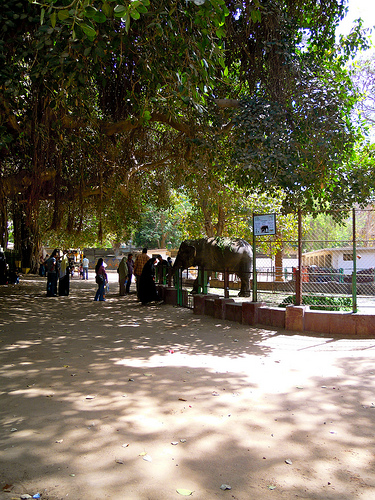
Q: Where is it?
A: This is at the park.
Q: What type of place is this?
A: It is a park.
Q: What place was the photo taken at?
A: It was taken at the park.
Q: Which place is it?
A: It is a park.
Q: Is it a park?
A: Yes, it is a park.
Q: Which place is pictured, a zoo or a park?
A: It is a park.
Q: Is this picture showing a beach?
A: No, the picture is showing a park.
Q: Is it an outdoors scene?
A: Yes, it is outdoors.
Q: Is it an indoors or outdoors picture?
A: It is outdoors.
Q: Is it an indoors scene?
A: No, it is outdoors.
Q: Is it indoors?
A: No, it is outdoors.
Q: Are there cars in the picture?
A: No, there are no cars.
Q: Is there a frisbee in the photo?
A: No, there are no frisbees.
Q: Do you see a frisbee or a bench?
A: No, there are no frisbees or benches.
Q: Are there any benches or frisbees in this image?
A: No, there are no frisbees or benches.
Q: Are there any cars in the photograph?
A: No, there are no cars.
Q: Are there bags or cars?
A: No, there are no cars or bags.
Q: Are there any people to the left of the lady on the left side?
A: No, the person is to the right of the lady.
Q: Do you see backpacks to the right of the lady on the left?
A: No, there is a person to the right of the lady.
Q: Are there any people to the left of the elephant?
A: Yes, there is a person to the left of the elephant.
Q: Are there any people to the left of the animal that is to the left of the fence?
A: Yes, there is a person to the left of the elephant.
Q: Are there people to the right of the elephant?
A: No, the person is to the left of the elephant.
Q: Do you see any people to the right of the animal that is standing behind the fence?
A: No, the person is to the left of the elephant.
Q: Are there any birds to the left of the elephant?
A: No, there is a person to the left of the elephant.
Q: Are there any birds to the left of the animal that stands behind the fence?
A: No, there is a person to the left of the elephant.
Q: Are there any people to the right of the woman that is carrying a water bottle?
A: Yes, there is a person to the right of the woman.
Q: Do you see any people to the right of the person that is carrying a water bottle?
A: Yes, there is a person to the right of the woman.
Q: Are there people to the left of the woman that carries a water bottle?
A: No, the person is to the right of the woman.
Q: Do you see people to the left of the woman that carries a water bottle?
A: No, the person is to the right of the woman.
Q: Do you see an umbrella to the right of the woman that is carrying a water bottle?
A: No, there is a person to the right of the woman.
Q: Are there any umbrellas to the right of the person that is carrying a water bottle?
A: No, there is a person to the right of the woman.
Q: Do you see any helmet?
A: No, there are no helmets.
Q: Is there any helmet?
A: No, there are no helmets.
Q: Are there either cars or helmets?
A: No, there are no helmets or cars.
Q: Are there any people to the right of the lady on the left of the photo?
A: Yes, there is a person to the right of the lady.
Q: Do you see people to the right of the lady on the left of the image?
A: Yes, there is a person to the right of the lady.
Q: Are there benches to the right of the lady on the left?
A: No, there is a person to the right of the lady.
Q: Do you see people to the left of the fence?
A: Yes, there is a person to the left of the fence.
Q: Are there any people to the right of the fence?
A: No, the person is to the left of the fence.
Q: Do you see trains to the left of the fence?
A: No, there is a person to the left of the fence.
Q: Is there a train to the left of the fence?
A: No, there is a person to the left of the fence.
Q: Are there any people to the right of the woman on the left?
A: Yes, there is a person to the right of the woman.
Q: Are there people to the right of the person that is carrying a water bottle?
A: Yes, there is a person to the right of the woman.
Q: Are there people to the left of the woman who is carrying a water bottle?
A: No, the person is to the right of the woman.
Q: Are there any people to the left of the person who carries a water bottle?
A: No, the person is to the right of the woman.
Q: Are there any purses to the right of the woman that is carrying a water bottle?
A: No, there is a person to the right of the woman.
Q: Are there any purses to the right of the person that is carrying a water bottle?
A: No, there is a person to the right of the woman.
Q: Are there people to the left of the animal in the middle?
A: Yes, there is a person to the left of the elephant.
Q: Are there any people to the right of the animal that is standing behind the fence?
A: No, the person is to the left of the elephant.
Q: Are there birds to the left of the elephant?
A: No, there is a person to the left of the elephant.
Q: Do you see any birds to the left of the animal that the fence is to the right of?
A: No, there is a person to the left of the elephant.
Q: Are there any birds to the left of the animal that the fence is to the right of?
A: No, there is a person to the left of the elephant.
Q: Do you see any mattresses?
A: No, there are no mattresses.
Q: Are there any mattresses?
A: No, there are no mattresses.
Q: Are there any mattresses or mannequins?
A: No, there are no mattresses or mannequins.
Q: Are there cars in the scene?
A: No, there are no cars.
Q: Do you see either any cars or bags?
A: No, there are no cars or bags.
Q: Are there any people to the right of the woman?
A: Yes, there are people to the right of the woman.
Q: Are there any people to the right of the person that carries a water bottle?
A: Yes, there are people to the right of the woman.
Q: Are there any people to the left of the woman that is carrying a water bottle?
A: No, the people are to the right of the woman.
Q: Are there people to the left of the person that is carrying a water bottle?
A: No, the people are to the right of the woman.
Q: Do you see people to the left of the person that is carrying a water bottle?
A: No, the people are to the right of the woman.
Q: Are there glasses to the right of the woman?
A: No, there are people to the right of the woman.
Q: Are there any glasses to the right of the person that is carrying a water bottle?
A: No, there are people to the right of the woman.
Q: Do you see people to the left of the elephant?
A: Yes, there are people to the left of the elephant.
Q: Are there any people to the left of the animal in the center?
A: Yes, there are people to the left of the elephant.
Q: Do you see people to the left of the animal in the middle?
A: Yes, there are people to the left of the elephant.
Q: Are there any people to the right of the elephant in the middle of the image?
A: No, the people are to the left of the elephant.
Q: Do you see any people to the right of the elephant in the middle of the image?
A: No, the people are to the left of the elephant.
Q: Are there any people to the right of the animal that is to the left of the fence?
A: No, the people are to the left of the elephant.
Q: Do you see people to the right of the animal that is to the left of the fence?
A: No, the people are to the left of the elephant.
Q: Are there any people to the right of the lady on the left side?
A: Yes, there are people to the right of the lady.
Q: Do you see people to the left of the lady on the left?
A: No, the people are to the right of the lady.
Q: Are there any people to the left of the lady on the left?
A: No, the people are to the right of the lady.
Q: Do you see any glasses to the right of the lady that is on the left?
A: No, there are people to the right of the lady.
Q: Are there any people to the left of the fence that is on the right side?
A: Yes, there are people to the left of the fence.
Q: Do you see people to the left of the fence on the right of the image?
A: Yes, there are people to the left of the fence.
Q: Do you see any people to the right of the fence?
A: No, the people are to the left of the fence.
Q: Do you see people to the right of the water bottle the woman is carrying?
A: Yes, there are people to the right of the water bottle.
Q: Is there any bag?
A: No, there are no bags.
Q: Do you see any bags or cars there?
A: No, there are no bags or cars.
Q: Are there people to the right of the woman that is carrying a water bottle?
A: Yes, there are people to the right of the woman.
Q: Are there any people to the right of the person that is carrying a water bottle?
A: Yes, there are people to the right of the woman.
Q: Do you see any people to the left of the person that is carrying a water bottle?
A: No, the people are to the right of the woman.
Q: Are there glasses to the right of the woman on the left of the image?
A: No, there are people to the right of the woman.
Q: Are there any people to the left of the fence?
A: Yes, there are people to the left of the fence.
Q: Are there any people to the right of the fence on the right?
A: No, the people are to the left of the fence.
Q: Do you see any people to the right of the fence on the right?
A: No, the people are to the left of the fence.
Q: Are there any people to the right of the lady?
A: Yes, there are people to the right of the lady.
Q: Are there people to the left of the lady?
A: No, the people are to the right of the lady.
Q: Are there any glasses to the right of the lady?
A: No, there are people to the right of the lady.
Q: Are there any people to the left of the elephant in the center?
A: Yes, there are people to the left of the elephant.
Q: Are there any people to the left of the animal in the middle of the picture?
A: Yes, there are people to the left of the elephant.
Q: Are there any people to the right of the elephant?
A: No, the people are to the left of the elephant.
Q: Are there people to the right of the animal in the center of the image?
A: No, the people are to the left of the elephant.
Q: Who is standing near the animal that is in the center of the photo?
A: The people are standing near the elephant.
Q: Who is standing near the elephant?
A: The people are standing near the elephant.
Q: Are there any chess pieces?
A: No, there are no chess pieces.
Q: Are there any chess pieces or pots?
A: No, there are no chess pieces or pots.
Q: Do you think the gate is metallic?
A: Yes, the gate is metallic.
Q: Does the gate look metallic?
A: Yes, the gate is metallic.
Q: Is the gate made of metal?
A: Yes, the gate is made of metal.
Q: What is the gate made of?
A: The gate is made of metal.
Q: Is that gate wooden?
A: No, the gate is metallic.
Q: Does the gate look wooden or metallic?
A: The gate is metallic.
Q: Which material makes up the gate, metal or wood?
A: The gate is made of metal.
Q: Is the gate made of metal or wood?
A: The gate is made of metal.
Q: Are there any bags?
A: No, there are no bags.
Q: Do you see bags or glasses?
A: No, there are no bags or glasses.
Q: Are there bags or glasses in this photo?
A: No, there are no bags or glasses.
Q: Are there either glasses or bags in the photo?
A: No, there are no bags or glasses.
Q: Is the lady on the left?
A: Yes, the lady is on the left of the image.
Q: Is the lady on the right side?
A: No, the lady is on the left of the image.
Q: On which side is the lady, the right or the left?
A: The lady is on the left of the image.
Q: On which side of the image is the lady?
A: The lady is on the left of the image.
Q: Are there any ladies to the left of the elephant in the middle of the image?
A: Yes, there is a lady to the left of the elephant.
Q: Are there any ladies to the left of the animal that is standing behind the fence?
A: Yes, there is a lady to the left of the elephant.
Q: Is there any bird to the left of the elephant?
A: No, there is a lady to the left of the elephant.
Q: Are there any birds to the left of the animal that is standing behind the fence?
A: No, there is a lady to the left of the elephant.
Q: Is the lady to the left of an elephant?
A: Yes, the lady is to the left of an elephant.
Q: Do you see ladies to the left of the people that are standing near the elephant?
A: Yes, there is a lady to the left of the people.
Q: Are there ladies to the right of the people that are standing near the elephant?
A: No, the lady is to the left of the people.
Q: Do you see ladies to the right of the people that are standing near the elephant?
A: No, the lady is to the left of the people.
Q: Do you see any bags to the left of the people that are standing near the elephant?
A: No, there is a lady to the left of the people.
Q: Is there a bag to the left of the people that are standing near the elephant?
A: No, there is a lady to the left of the people.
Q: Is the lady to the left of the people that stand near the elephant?
A: Yes, the lady is to the left of the people.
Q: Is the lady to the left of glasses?
A: No, the lady is to the left of the people.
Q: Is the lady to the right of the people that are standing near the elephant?
A: No, the lady is to the left of the people.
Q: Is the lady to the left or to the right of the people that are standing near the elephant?
A: The lady is to the left of the people.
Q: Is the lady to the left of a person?
A: Yes, the lady is to the left of a person.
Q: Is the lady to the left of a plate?
A: No, the lady is to the left of a person.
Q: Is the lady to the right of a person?
A: No, the lady is to the left of a person.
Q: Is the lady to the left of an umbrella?
A: No, the lady is to the left of a person.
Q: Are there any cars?
A: No, there are no cars.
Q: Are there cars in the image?
A: No, there are no cars.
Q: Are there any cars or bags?
A: No, there are no cars or bags.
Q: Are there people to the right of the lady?
A: Yes, there is a person to the right of the lady.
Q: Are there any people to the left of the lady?
A: No, the person is to the right of the lady.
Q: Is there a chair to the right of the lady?
A: No, there is a person to the right of the lady.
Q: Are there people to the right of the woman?
A: Yes, there is a person to the right of the woman.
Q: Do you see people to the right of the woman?
A: Yes, there is a person to the right of the woman.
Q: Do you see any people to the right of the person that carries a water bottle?
A: Yes, there is a person to the right of the woman.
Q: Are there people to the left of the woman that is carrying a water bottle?
A: No, the person is to the right of the woman.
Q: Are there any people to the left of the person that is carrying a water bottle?
A: No, the person is to the right of the woman.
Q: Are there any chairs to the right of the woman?
A: No, there is a person to the right of the woman.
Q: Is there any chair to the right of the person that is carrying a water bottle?
A: No, there is a person to the right of the woman.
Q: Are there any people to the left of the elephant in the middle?
A: Yes, there is a person to the left of the elephant.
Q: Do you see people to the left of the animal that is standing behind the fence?
A: Yes, there is a person to the left of the elephant.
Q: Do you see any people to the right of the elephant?
A: No, the person is to the left of the elephant.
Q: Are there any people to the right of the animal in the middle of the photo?
A: No, the person is to the left of the elephant.